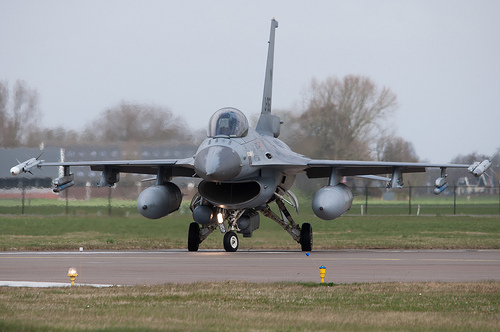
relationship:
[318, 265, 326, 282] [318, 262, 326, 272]
post with light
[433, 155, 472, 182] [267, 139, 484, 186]
edge of wing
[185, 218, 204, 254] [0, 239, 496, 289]
wheels on runway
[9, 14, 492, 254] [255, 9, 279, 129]
plane has tail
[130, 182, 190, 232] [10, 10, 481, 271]
engine on plane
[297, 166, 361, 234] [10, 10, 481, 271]
engine on plane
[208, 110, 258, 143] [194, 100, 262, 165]
window on cockpit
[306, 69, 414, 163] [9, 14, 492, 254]
tree behind plane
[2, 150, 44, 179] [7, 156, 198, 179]
edge of plane wing